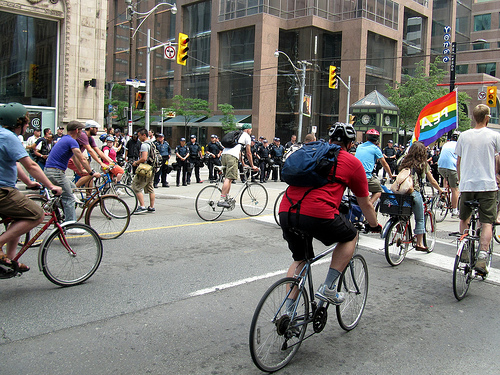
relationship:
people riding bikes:
[9, 114, 499, 186] [241, 95, 422, 357]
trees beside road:
[102, 73, 237, 144] [152, 185, 307, 371]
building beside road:
[9, 57, 133, 207] [45, 89, 457, 374]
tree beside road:
[389, 70, 471, 169] [14, 172, 498, 375]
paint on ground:
[186, 253, 338, 300] [0, 152, 497, 373]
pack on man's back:
[255, 113, 357, 206] [259, 127, 380, 210]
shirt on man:
[46, 135, 80, 171] [43, 117, 98, 230]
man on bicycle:
[453, 102, 498, 274] [448, 198, 490, 303]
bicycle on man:
[448, 198, 490, 303] [216, 121, 261, 208]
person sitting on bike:
[0, 102, 63, 273] [3, 185, 120, 290]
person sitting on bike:
[277, 119, 383, 333] [249, 220, 369, 371]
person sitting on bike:
[392, 142, 444, 252] [382, 204, 437, 267]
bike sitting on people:
[2, 189, 104, 286] [0, 103, 62, 274]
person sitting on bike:
[277, 119, 383, 333] [247, 211, 377, 372]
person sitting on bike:
[1, 98, 66, 280] [2, 179, 104, 290]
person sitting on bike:
[392, 142, 444, 252] [371, 187, 437, 262]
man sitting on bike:
[43, 120, 101, 235] [450, 200, 498, 297]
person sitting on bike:
[70, 116, 116, 208] [44, 170, 134, 238]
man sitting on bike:
[218, 123, 258, 206] [192, 157, 273, 223]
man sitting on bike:
[453, 104, 500, 274] [447, 200, 499, 301]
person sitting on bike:
[353, 132, 395, 214] [244, 227, 382, 372]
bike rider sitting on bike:
[437, 131, 460, 219] [421, 185, 460, 227]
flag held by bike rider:
[407, 83, 463, 143] [434, 126, 461, 216]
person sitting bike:
[277, 119, 383, 333] [190, 160, 272, 226]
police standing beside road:
[132, 125, 281, 177] [14, 172, 498, 375]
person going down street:
[277, 119, 383, 333] [0, 174, 500, 367]